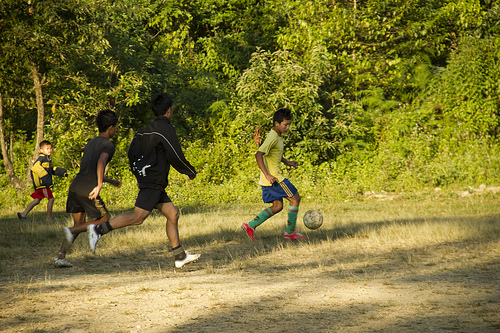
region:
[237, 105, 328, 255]
A boy kicking a soccerball.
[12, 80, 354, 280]
A group of boys playing soccer together.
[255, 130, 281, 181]
A yellow t-shirt.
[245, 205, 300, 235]
Green tube socks with a red stripe around the tops of them.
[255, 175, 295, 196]
A pair of blue sports shorts with yellow stripes down the side.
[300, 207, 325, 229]
A soccer ball.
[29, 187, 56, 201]
A pair of red sports shorts with whites stripes down the side.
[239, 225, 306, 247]
A pair of red shoes.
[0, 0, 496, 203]
Trees and shrubs.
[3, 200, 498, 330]
Dead looking grass and dry dirt.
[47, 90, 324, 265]
Children playing soccer.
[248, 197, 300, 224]
A boy wearing green and red socks.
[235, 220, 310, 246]
Bright colored tennis shoes.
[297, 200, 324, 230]
A white soccer ball.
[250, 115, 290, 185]
A boy wearing a yellow shirt.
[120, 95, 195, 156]
A boy wearing a black jacket with a stripe across the back.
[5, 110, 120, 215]
A younger boy on the left side of an older boy.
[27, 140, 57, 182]
A young boy wearing a yellow and black jacket.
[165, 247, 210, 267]
Boy wearing white tennis shoes.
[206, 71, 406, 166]
Green shubbery behind the boy.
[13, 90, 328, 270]
Boys playing soccer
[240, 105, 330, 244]
Boy about to kick a ball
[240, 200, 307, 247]
Bright green knee socks with red stripe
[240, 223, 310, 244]
Red shoes in motion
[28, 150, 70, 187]
Black and yellow sports jacket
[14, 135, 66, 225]
Little boy in red shorts running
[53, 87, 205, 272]
Two boys running together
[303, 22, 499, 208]
A lot of green vegetation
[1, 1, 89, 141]
Shaded forest area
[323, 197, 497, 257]
Partly shaded grass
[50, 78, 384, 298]
three boys playing soccer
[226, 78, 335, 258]
a boy playing soccer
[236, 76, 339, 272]
A boy with a soccer ball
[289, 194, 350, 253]
a soccer ball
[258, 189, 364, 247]
a soccer ball off the ground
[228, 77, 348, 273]
A boy wearing a yellow shirt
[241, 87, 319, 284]
A boy wearing blue shorts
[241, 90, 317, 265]
A boy wearing green sox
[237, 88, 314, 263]
A boy wearing red shoes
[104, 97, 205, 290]
A boy wearing white shoes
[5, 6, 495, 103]
Green leaves on trees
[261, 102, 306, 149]
A boy with black hair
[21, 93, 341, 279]
Four boys playing with a ball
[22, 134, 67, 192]
A boy wearing a black and yellow jacket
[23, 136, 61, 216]
A boy wearing red shorts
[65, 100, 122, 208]
A boy wearing a black t-shirt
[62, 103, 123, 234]
A boy wearing black shorts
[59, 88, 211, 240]
Two boys wearing black shorts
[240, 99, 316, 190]
A boy wearing a yellow shirt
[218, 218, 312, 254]
A boy wearing red shoes